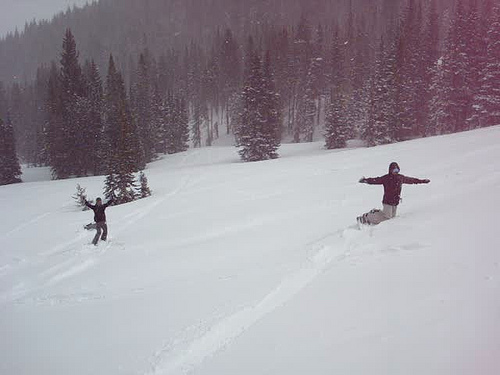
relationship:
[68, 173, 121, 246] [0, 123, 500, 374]
person standing in flat snow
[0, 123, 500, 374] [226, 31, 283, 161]
flat snow on a pine trees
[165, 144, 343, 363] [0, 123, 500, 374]
trail in flat snow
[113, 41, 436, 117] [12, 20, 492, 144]
pine trees in background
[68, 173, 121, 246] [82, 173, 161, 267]
person standing with a hooded coat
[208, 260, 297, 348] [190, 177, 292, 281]
flat snow on a hill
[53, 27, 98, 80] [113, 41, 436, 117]
top of a pine trees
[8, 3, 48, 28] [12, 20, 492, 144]
dark sky over trees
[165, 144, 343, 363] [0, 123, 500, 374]
ground covered with flat snow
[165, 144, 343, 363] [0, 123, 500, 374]
ground covered in flat snow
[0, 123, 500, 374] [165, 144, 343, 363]
flat snow covering ground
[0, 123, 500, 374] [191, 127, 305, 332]
flat snow covering ground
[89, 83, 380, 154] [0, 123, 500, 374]
trees in flat snow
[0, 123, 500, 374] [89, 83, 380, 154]
flat snow in trees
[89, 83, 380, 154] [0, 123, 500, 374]
trees with flat snow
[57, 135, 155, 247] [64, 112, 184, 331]
person in distance going uphill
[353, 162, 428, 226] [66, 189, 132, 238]
person raising hands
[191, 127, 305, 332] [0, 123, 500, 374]
ground covered in flat snow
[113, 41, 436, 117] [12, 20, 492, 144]
pine trees are in background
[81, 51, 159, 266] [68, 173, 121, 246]
large tree near person standing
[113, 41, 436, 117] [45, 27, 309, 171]
pine trees in distance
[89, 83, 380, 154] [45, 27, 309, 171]
trees cover hill in distance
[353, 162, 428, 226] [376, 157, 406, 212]
person wearing jacket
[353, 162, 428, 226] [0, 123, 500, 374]
person kneeling in flat snow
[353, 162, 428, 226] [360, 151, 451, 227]
person holding their arms out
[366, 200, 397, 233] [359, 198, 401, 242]
pants are light tan in color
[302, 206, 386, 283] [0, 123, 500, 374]
person made deep tracks in flat snow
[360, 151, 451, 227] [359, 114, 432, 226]
person wears a black jacket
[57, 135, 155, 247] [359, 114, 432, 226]
persons wearing a black jacket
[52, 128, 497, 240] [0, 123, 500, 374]
two skiers flat snow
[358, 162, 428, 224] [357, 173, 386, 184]
person has arm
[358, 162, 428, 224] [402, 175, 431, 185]
person has arm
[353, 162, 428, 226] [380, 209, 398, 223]
person bent over on knees